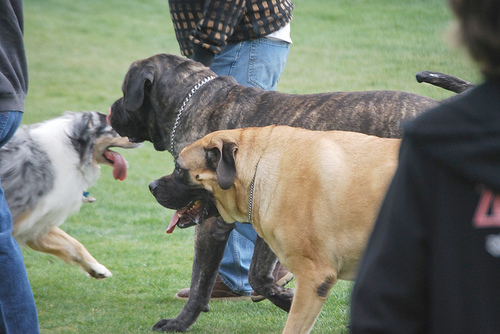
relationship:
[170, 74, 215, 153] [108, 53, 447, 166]
chain on dog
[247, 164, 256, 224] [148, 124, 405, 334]
chain around dog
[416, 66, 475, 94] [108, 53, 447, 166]
tail of dog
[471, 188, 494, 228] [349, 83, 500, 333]
letter ont he hoodie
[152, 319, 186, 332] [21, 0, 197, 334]
paw on grass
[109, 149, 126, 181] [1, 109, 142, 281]
tounge hanging from dog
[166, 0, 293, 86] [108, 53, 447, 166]
man behind dog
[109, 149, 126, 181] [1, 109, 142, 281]
tounge sticking out of dog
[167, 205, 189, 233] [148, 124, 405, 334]
tounge sticking out of dog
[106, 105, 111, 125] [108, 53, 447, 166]
tounge sticking out of dog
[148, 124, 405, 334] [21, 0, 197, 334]
dog on grass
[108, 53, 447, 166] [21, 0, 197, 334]
dog on grass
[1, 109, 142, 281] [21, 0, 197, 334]
dog on grass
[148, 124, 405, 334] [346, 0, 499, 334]
dog beside people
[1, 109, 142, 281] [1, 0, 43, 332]
dog beside people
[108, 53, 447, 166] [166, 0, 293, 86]
dog beside man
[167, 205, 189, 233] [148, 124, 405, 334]
tounge in mouth of dog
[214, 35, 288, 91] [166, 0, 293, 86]
jeans on man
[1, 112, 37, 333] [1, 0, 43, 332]
jeans on people